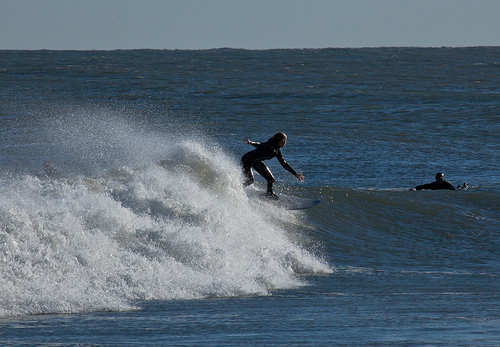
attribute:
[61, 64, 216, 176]
water — blue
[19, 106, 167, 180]
spray — white, white water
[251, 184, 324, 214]
surf board — blue 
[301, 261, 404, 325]
water — blue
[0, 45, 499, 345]
water — blue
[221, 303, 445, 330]
surface — choppy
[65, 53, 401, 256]
water — blue